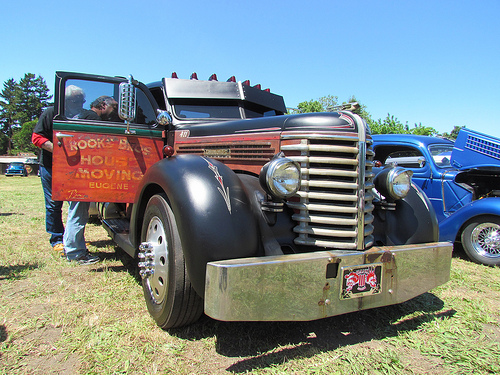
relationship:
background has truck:
[173, 25, 306, 42] [356, 106, 499, 296]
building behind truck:
[2, 150, 36, 164] [356, 106, 499, 296]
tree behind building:
[3, 70, 50, 115] [2, 150, 36, 164]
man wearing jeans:
[35, 147, 62, 255] [63, 199, 90, 252]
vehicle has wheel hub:
[38, 61, 470, 340] [156, 152, 245, 228]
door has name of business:
[56, 70, 148, 199] [68, 134, 151, 192]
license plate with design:
[342, 267, 386, 298] [353, 272, 374, 291]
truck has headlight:
[356, 106, 499, 296] [260, 151, 306, 197]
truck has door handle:
[356, 106, 499, 296] [52, 129, 76, 145]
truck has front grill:
[356, 106, 499, 296] [301, 130, 371, 186]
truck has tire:
[356, 106, 499, 296] [146, 275, 182, 324]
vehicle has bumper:
[38, 61, 470, 340] [6, 165, 27, 171]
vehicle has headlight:
[38, 61, 470, 340] [260, 151, 306, 197]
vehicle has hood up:
[38, 61, 470, 340] [451, 129, 499, 181]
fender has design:
[314, 257, 403, 265] [353, 272, 374, 291]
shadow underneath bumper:
[307, 325, 395, 347] [6, 165, 27, 171]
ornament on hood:
[324, 100, 366, 113] [292, 109, 338, 137]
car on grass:
[5, 162, 28, 177] [12, 239, 37, 259]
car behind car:
[5, 157, 28, 181] [5, 162, 28, 177]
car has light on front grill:
[5, 162, 28, 177] [291, 135, 374, 249]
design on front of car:
[353, 272, 374, 291] [5, 162, 28, 177]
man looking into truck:
[35, 147, 62, 255] [356, 106, 499, 296]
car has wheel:
[5, 157, 28, 181] [456, 214, 497, 267]